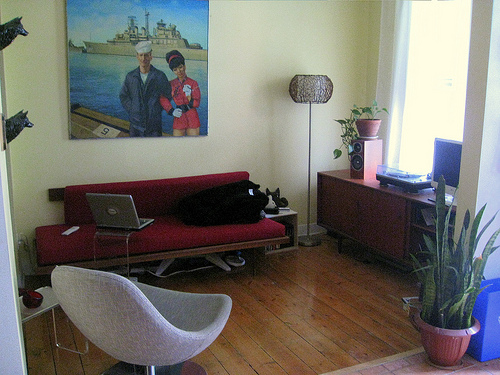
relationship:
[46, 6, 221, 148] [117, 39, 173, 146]
painting of sailor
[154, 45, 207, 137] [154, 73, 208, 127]
woman has red outfit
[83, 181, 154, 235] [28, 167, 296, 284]
laptop on couch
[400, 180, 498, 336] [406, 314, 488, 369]
plant in brown container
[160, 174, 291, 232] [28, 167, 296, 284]
black object on couch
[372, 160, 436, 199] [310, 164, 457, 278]
record player on top of cabinet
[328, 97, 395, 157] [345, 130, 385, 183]
plant on top of speaker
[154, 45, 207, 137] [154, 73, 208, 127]
woman wears red outfit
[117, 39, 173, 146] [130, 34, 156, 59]
sailor has hat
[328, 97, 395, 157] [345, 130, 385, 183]
plant on speaker